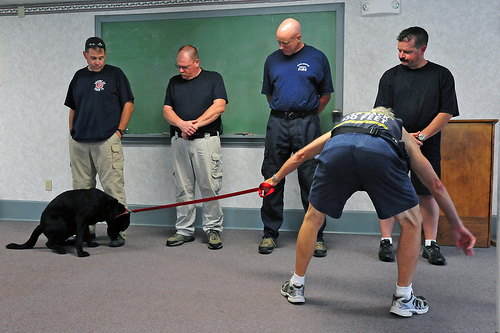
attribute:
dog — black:
[1, 186, 128, 258]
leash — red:
[117, 177, 275, 219]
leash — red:
[127, 177, 278, 217]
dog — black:
[7, 188, 127, 261]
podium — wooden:
[420, 117, 498, 248]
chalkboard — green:
[93, 12, 344, 139]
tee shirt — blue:
[259, 44, 334, 111]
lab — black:
[28, 177, 134, 267]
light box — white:
[360, 3, 402, 14]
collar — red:
[117, 207, 130, 222]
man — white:
[57, 36, 140, 252]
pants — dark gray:
[170, 130, 227, 235]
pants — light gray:
[165, 131, 226, 232]